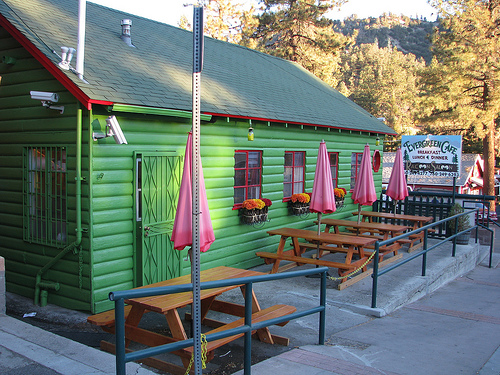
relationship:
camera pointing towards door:
[94, 111, 129, 149] [135, 151, 187, 289]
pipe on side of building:
[30, 100, 99, 316] [0, 0, 399, 316]